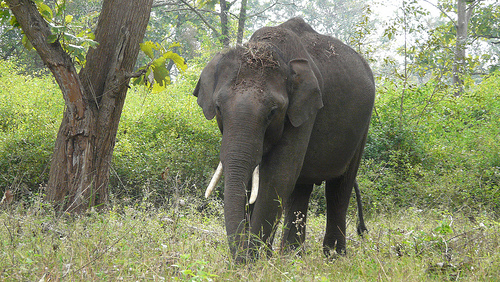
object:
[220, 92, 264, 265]
trunk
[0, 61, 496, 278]
grass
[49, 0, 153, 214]
tree trunk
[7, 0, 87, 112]
branch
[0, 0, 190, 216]
tree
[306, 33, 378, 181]
side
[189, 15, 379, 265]
elephant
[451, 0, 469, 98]
trees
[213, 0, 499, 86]
sky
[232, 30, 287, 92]
debris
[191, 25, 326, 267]
elephant's head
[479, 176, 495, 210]
bushes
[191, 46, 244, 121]
elephant's ears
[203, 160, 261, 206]
elephant's tusk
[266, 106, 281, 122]
eyes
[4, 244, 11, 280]
plants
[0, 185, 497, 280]
ground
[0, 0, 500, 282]
picture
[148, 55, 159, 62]
leaves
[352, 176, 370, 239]
tail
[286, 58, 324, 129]
ear